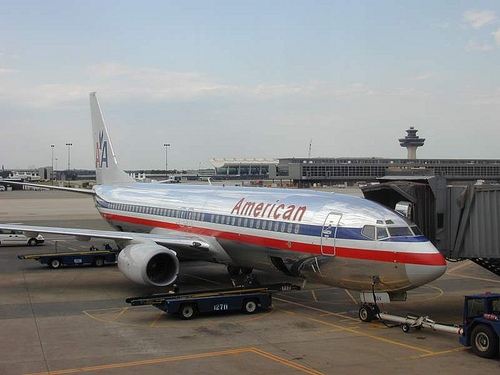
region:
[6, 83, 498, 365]
scene outside of an airport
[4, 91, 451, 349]
American airlines parked plane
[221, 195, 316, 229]
the word American on side of plane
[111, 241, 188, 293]
engine on right side of plane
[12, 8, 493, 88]
blue sky with white clouds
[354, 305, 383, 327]
front wheels of a plane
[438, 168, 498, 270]
tunnel for passengers to board plane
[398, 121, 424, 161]
signal tower in the distance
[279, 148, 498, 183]
airport terminal in the background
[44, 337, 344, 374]
yellow painted lines on the pavement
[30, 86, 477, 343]
large jet airplane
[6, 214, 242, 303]
jet engine attached to a plane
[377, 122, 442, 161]
airport control tower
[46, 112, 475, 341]
American Airlines airplane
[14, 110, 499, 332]
airplane at the terminal gate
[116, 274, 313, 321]
airport luggage cart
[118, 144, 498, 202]
large airport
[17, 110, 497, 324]
airplane parked at an airport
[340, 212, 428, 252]
windows of an airplane cockpit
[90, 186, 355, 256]
passenger windows on a large jet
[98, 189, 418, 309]
this is a jet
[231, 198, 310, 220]
the jet is written American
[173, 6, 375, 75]
this is the sky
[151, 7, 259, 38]
the sky is blue in color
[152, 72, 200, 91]
these are the clouds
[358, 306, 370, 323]
this is the wheel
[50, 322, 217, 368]
this is the runway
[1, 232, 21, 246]
this is a car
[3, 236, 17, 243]
the car is white in color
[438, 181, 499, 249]
this is a container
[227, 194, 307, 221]
The word AMERICAN on the side of a plane.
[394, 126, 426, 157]
Control tower sticking up to the right.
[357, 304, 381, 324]
Two front wheels of an American airline.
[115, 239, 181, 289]
Left side engine of an airplane.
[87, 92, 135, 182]
Tail of an American Airlines plane.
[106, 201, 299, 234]
Small windows on this side of the plane.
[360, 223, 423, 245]
Front windshields of an American Airlines airplane.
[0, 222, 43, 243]
White car to the left of an airplane.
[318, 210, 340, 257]
Front side door of an American Airlines plane.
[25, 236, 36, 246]
Front passenger side wheel of a white car.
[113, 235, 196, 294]
Engine on a plane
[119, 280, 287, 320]
Cart on a runway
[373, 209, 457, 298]
Nose on a plane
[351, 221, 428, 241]
Windows on a plane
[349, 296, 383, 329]
Wheel on a plane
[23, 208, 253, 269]
Wing on a plane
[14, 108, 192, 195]
Tail on a plane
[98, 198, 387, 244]
Windows on the side of a plane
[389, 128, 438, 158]
Airport control tower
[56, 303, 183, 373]
Yellow lines on a runway